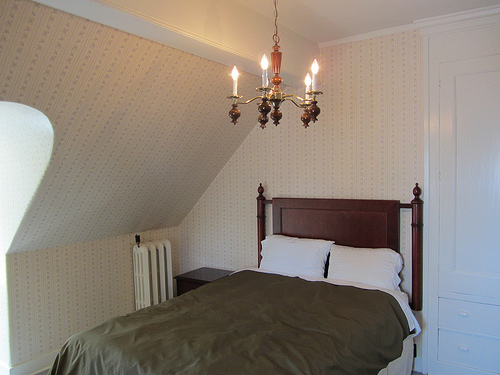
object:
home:
[0, 30, 498, 372]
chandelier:
[226, 2, 323, 130]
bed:
[66, 182, 423, 374]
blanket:
[25, 268, 411, 373]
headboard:
[256, 182, 424, 312]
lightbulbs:
[308, 58, 321, 99]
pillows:
[325, 244, 407, 291]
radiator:
[131, 238, 177, 309]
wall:
[4, 225, 179, 366]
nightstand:
[173, 265, 234, 297]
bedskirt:
[372, 333, 413, 374]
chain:
[271, 0, 280, 51]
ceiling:
[240, 1, 498, 41]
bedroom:
[2, 2, 496, 372]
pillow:
[258, 233, 335, 281]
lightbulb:
[230, 64, 241, 82]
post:
[410, 181, 423, 312]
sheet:
[223, 268, 420, 334]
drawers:
[436, 297, 500, 343]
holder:
[227, 88, 245, 126]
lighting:
[300, 71, 312, 105]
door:
[425, 17, 499, 374]